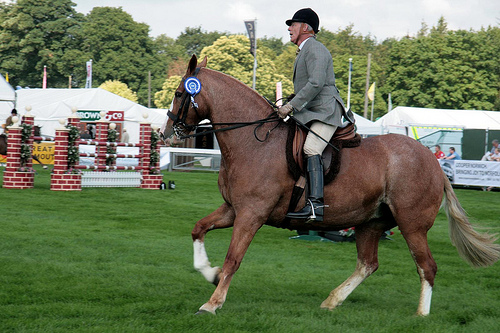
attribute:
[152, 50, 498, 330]
horse — dressage, IN COMPETITION